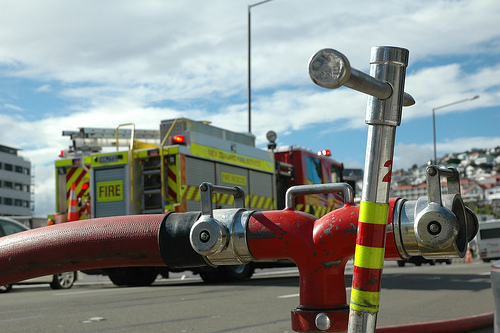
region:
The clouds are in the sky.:
[35, 8, 226, 87]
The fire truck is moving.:
[64, 119, 341, 229]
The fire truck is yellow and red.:
[50, 110, 330, 217]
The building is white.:
[3, 144, 51, 242]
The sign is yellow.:
[91, 182, 133, 209]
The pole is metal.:
[298, 32, 378, 332]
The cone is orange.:
[57, 182, 92, 224]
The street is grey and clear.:
[53, 289, 273, 324]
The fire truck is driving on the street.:
[32, 114, 407, 291]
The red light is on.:
[157, 124, 197, 156]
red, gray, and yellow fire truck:
[40, 109, 376, 297]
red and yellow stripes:
[347, 197, 386, 315]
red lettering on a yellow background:
[93, 181, 125, 201]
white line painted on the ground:
[276, 288, 304, 300]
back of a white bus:
[473, 215, 498, 262]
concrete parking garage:
[1, 143, 38, 224]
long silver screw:
[307, 43, 419, 110]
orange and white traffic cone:
[63, 178, 84, 223]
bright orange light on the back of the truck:
[169, 132, 186, 146]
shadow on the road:
[265, 274, 485, 294]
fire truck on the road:
[58, 95, 354, 276]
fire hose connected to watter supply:
[204, 70, 393, 300]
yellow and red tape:
[354, 195, 389, 319]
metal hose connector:
[178, 169, 274, 284]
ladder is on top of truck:
[66, 111, 203, 153]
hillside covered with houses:
[400, 145, 499, 190]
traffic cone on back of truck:
[57, 173, 91, 240]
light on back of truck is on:
[164, 129, 194, 145]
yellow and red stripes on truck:
[179, 181, 286, 205]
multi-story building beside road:
[3, 138, 37, 214]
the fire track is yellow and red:
[99, 110, 344, 200]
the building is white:
[9, 150, 41, 212]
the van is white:
[479, 222, 499, 264]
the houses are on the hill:
[416, 147, 498, 187]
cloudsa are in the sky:
[82, 33, 245, 78]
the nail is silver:
[302, 53, 424, 102]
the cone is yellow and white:
[62, 180, 84, 219]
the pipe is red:
[50, 219, 150, 262]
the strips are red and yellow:
[351, 200, 395, 309]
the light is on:
[167, 135, 189, 147]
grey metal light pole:
[242, 6, 262, 131]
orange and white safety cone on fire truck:
[64, 182, 80, 222]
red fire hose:
[10, 199, 160, 303]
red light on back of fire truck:
[168, 128, 193, 147]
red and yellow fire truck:
[35, 107, 360, 212]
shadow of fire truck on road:
[386, 263, 488, 305]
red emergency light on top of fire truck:
[311, 143, 335, 158]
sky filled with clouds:
[3, 0, 245, 117]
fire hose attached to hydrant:
[8, 184, 476, 327]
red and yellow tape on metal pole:
[352, 196, 392, 319]